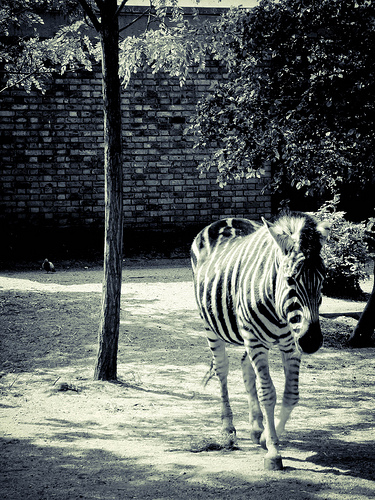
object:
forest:
[233, 11, 362, 140]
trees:
[186, 5, 374, 218]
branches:
[71, 0, 145, 51]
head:
[274, 221, 329, 355]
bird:
[41, 258, 55, 274]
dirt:
[18, 273, 72, 299]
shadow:
[275, 430, 375, 483]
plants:
[305, 197, 374, 276]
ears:
[261, 216, 296, 256]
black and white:
[211, 225, 286, 282]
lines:
[216, 241, 250, 279]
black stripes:
[201, 278, 276, 311]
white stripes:
[214, 300, 277, 350]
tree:
[0, 4, 219, 379]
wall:
[142, 114, 164, 154]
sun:
[39, 3, 197, 63]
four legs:
[210, 344, 301, 455]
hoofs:
[264, 457, 282, 471]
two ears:
[260, 208, 348, 269]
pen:
[48, 45, 262, 216]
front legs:
[245, 346, 276, 450]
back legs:
[207, 334, 234, 428]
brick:
[143, 128, 214, 199]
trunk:
[99, 47, 124, 343]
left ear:
[314, 209, 348, 248]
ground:
[114, 396, 351, 473]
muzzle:
[296, 325, 315, 351]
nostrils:
[296, 325, 323, 355]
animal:
[189, 209, 345, 471]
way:
[205, 253, 373, 376]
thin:
[100, 149, 132, 178]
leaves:
[212, 30, 251, 104]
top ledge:
[136, 0, 270, 25]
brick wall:
[0, 11, 274, 230]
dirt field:
[68, 349, 202, 452]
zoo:
[1, 4, 375, 498]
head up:
[277, 210, 321, 256]